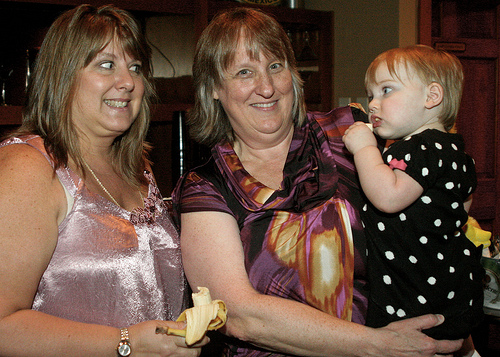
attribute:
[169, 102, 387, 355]
shirt — black, multi colored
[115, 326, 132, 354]
watch — silver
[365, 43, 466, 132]
hair — blonde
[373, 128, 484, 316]
dress — polka dot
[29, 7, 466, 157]
hair — blonde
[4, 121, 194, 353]
shirt — silver